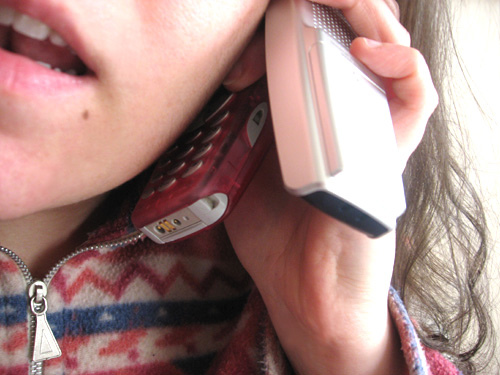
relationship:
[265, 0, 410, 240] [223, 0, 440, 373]
phone in hand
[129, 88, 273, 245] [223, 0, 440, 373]
phone in hand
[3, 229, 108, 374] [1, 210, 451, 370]
zipper on jacket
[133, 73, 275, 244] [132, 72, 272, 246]
case on phone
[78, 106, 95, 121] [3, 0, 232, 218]
mole on girls face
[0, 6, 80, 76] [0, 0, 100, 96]
teeth in mouth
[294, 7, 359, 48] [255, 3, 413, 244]
speaker on back of phone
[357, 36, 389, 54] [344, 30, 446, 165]
nail on finger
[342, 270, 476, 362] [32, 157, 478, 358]
sleeve on jacket